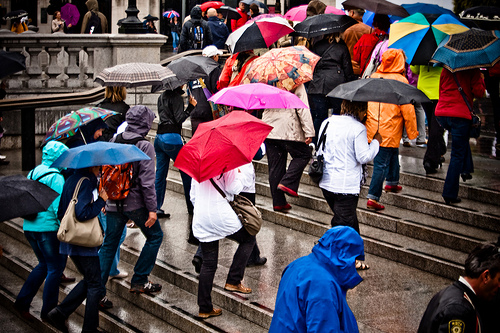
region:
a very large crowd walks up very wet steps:
[1, 0, 499, 331]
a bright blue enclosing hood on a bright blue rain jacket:
[262, 222, 369, 332]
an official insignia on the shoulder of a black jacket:
[443, 315, 464, 330]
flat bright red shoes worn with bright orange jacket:
[356, 45, 423, 212]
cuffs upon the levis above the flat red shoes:
[361, 177, 401, 202]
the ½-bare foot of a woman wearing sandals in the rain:
[349, 257, 374, 272]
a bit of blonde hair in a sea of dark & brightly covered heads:
[101, 81, 131, 102]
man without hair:
[203, 5, 220, 19]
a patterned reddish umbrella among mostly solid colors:
[238, 40, 325, 95]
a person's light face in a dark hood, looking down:
[79, 112, 109, 147]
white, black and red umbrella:
[225, 10, 291, 50]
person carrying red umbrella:
[171, 107, 256, 322]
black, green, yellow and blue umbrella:
[385, 5, 465, 65]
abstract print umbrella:
[240, 37, 320, 92]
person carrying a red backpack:
[92, 105, 162, 295]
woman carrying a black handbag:
[305, 97, 377, 269]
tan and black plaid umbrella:
[91, 60, 176, 105]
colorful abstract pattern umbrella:
[42, 105, 117, 140]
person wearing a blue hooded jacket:
[261, 221, 366, 327]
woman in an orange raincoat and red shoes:
[363, 46, 416, 209]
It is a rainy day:
[78, 25, 453, 257]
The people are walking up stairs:
[71, 37, 405, 299]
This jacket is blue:
[259, 185, 390, 314]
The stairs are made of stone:
[18, 27, 471, 329]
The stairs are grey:
[44, 12, 421, 282]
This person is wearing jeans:
[73, 93, 172, 328]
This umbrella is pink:
[189, 82, 320, 114]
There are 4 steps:
[296, 147, 453, 327]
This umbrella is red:
[179, 124, 296, 205]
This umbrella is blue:
[56, 124, 146, 184]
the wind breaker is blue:
[275, 205, 381, 317]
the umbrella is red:
[166, 115, 268, 175]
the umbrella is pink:
[217, 78, 305, 123]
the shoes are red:
[262, 178, 430, 228]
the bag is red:
[97, 141, 138, 213]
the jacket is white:
[311, 110, 384, 221]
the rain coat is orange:
[368, 45, 425, 160]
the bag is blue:
[159, 129, 184, 154]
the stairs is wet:
[263, 210, 463, 257]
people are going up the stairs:
[146, 12, 407, 181]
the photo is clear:
[1, 5, 499, 332]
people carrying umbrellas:
[0, 0, 499, 191]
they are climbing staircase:
[400, 200, 460, 256]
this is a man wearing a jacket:
[267, 226, 375, 326]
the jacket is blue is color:
[268, 226, 370, 332]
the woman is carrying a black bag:
[308, 151, 323, 182]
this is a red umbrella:
[175, 111, 263, 171]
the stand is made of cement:
[20, 33, 165, 61]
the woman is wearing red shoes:
[366, 200, 381, 208]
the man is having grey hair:
[463, 246, 498, 266]